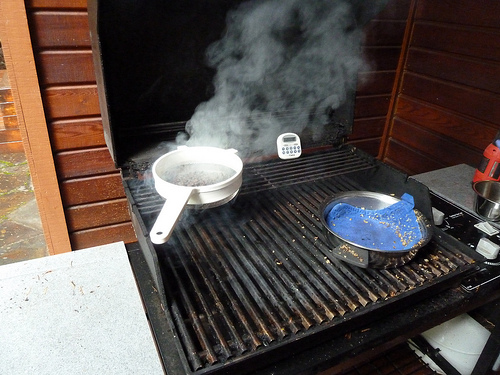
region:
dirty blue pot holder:
[331, 190, 421, 247]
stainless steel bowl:
[319, 187, 431, 269]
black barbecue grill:
[87, 0, 499, 374]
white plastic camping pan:
[145, 142, 244, 248]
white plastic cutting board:
[0, 240, 166, 372]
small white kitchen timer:
[275, 130, 301, 158]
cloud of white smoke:
[138, 0, 368, 226]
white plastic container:
[411, 314, 499, 374]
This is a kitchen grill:
[115, 125, 498, 365]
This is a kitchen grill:
[133, 109, 493, 373]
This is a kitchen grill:
[136, 108, 453, 371]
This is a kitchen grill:
[128, 108, 492, 360]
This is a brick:
[60, 221, 152, 247]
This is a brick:
[59, 198, 139, 226]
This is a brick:
[57, 174, 132, 204]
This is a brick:
[42, 150, 124, 177]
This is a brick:
[49, 116, 115, 146]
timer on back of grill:
[265, 129, 313, 166]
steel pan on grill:
[320, 180, 412, 276]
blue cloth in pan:
[329, 186, 433, 288]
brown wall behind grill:
[17, 57, 113, 240]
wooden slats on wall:
[47, 84, 118, 241]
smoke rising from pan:
[179, 50, 286, 142]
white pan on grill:
[160, 80, 229, 237]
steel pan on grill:
[322, 184, 436, 299]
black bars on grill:
[226, 170, 321, 366]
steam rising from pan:
[186, 31, 350, 152]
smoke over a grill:
[137, 3, 379, 260]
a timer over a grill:
[266, 126, 308, 168]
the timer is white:
[274, 128, 304, 163]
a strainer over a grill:
[131, 133, 258, 253]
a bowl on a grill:
[125, 115, 258, 263]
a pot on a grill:
[315, 169, 437, 289]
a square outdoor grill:
[109, 127, 486, 372]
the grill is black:
[106, 120, 488, 368]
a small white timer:
[271, 126, 309, 163]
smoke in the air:
[153, 0, 388, 211]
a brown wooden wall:
[8, 4, 498, 240]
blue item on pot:
[328, 189, 426, 256]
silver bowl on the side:
[467, 170, 498, 222]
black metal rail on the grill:
[162, 241, 217, 366]